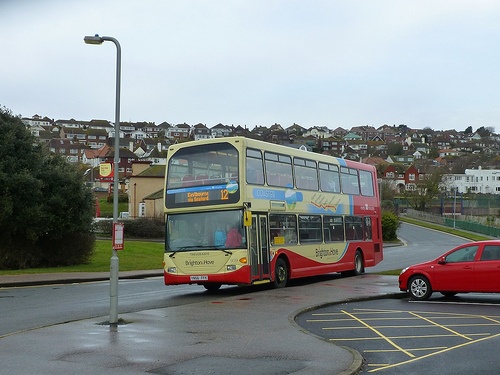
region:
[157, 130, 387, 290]
double decker yellow and red bus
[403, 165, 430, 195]
house behind the yellow and red bus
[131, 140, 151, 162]
house behind the yellow and red bus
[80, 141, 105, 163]
house behind the yellow and red bus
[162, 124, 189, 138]
house behind the yellow and red bus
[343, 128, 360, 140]
house behind the yellow and red bus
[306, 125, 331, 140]
house behind the yellow and red bus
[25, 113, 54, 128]
house behind the yellow and red bus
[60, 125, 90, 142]
house behind the yellow and red bus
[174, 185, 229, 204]
bus number and route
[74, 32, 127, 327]
a pole lamp on street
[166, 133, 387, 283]
red and yellow double decker bus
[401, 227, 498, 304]
a parked red car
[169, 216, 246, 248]
front window of the bus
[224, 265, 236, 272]
a light on the front of bus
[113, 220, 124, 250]
red and white sign on pole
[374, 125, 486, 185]
several housing units in background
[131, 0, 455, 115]
the light blue sky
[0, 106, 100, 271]
evergreen bush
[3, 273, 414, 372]
concrete paving with glistening wet spots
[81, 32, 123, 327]
overhead street light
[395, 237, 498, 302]
parked red car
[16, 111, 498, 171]
rows of hillside housing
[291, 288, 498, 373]
yellow criss-cross lines on asphalt paving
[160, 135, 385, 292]
yellow and red double decked bus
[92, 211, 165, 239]
row of low hedges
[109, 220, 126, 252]
red and white sign attached to pole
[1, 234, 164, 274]
grass lawn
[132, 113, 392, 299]
Two level bus with big windows.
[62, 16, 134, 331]
Light pole with red and white sign on it.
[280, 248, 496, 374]
Yellow criss cross lines painted in parking lot.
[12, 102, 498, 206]
Ridge covered in many buildings.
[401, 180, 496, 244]
Fence along side sidewalk.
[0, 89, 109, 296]
Large tree near sidewalk.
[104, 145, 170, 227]
Large tan building with green roof.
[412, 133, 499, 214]
Big white building at bottom of ridge.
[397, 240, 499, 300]
A red parked vehicle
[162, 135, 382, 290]
A large double decker bus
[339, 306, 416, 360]
Yellow line on dark pavement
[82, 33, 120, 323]
A tall street light.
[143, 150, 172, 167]
A building in a city.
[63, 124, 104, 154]
A building in a city.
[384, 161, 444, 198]
A building in a city.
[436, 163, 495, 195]
A building in a city.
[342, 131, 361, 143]
A building in a city.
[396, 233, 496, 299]
A car in a parking lot.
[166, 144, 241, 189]
glass is clear and clean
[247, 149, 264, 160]
glass is clear and clean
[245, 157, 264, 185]
glass is clear and clean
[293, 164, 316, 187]
glass is clear and clean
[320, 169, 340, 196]
glass is clear and clean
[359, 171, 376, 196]
glass is clear and clean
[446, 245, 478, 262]
glass is clear and clean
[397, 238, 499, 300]
red car parked in parking lot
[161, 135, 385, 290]
double-decker bus driving on street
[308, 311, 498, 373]
yellow lines painted in parking lot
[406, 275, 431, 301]
tire on red car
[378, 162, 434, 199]
large brick home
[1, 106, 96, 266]
tree growing on grass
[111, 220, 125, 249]
sign on street lamp